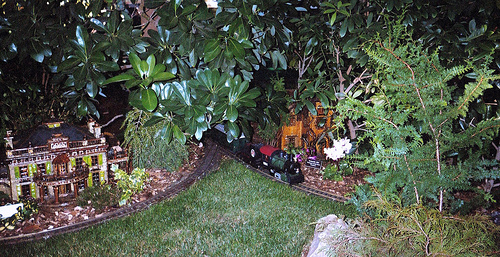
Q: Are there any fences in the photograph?
A: No, there are no fences.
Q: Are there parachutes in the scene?
A: No, there are no parachutes.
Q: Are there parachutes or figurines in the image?
A: No, there are no parachutes or figurines.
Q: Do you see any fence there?
A: No, there are no fences.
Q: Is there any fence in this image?
A: No, there are no fences.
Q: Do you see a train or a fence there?
A: Yes, there is a train.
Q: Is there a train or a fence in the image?
A: Yes, there is a train.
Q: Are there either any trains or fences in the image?
A: Yes, there is a train.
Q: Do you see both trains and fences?
A: No, there is a train but no fences.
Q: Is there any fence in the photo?
A: No, there are no fences.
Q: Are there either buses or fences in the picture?
A: No, there are no fences or buses.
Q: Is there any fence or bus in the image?
A: No, there are no fences or buses.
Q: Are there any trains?
A: Yes, there is a train.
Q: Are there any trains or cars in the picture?
A: Yes, there is a train.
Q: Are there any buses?
A: No, there are no buses.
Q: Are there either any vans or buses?
A: No, there are no buses or vans.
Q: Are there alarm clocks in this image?
A: No, there are no alarm clocks.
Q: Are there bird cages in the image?
A: No, there are no bird cages.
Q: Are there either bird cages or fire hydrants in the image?
A: No, there are no bird cages or fire hydrants.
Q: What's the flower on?
A: The flower is on the shrub.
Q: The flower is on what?
A: The flower is on the shrub.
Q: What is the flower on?
A: The flower is on the shrub.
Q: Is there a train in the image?
A: Yes, there is a train.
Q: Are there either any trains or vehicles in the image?
A: Yes, there is a train.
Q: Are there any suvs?
A: No, there are no suvs.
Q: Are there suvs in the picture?
A: No, there are no suvs.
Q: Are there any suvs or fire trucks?
A: No, there are no suvs or fire trucks.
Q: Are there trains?
A: Yes, there is a train.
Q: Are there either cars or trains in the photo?
A: Yes, there is a train.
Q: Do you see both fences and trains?
A: No, there is a train but no fences.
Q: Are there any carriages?
A: No, there are no carriages.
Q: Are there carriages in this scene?
A: No, there are no carriages.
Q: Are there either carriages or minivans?
A: No, there are no carriages or minivans.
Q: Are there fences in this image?
A: No, there are no fences.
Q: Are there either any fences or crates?
A: No, there are no fences or crates.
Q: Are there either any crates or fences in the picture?
A: No, there are no fences or crates.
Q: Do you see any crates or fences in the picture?
A: No, there are no fences or crates.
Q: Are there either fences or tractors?
A: No, there are no fences or tractors.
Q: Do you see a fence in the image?
A: No, there are no fences.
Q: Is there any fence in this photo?
A: No, there are no fences.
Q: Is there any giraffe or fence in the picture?
A: No, there are no fences or giraffes.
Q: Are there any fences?
A: No, there are no fences.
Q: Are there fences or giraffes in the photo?
A: No, there are no fences or giraffes.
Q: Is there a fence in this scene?
A: No, there are no fences.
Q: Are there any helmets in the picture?
A: No, there are no helmets.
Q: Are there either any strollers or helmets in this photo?
A: No, there are no helmets or strollers.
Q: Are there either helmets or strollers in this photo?
A: No, there are no helmets or strollers.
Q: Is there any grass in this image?
A: Yes, there is grass.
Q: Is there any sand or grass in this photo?
A: Yes, there is grass.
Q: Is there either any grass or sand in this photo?
A: Yes, there is grass.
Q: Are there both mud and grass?
A: No, there is grass but no mud.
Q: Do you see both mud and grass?
A: No, there is grass but no mud.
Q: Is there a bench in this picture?
A: No, there are no benches.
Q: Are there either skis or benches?
A: No, there are no benches or skis.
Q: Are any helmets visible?
A: No, there are no helmets.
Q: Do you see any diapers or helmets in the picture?
A: No, there are no helmets or diapers.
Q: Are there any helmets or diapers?
A: No, there are no helmets or diapers.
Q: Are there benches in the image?
A: No, there are no benches.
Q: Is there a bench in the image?
A: No, there are no benches.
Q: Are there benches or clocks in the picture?
A: No, there are no benches or clocks.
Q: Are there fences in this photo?
A: No, there are no fences.